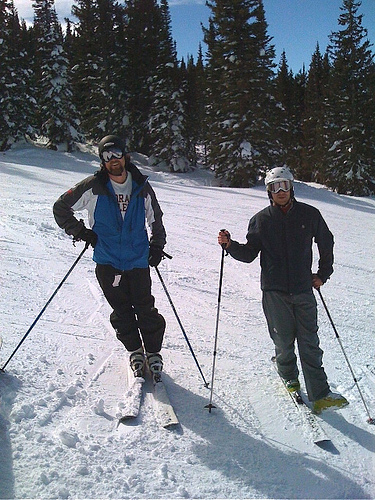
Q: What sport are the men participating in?
A: Skiing.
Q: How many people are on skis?
A: 2.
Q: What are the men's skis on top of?
A: Snow.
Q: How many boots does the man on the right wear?
A: 2.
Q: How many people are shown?
A: 2.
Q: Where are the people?
A: Mountainside.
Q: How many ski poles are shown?
A: 4.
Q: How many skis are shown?
A: 3.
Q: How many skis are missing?
A: 1.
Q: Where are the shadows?
A: On the snow.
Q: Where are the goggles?
A: The men's faces.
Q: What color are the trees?
A: Green.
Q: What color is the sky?
A: Blue.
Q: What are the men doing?
A: Skiing.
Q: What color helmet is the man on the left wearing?
A: Black.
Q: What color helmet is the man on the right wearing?
A: White.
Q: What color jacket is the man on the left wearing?
A: Blue and black.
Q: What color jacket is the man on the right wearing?
A: Black.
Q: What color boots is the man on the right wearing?
A: Yellow.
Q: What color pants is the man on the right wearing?
A: Grey.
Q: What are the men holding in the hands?
A: Ski poles.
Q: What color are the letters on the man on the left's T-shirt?
A: Red.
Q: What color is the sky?
A: Blue.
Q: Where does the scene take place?
A: On a ski slope.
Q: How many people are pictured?
A: Two.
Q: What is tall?
A: Pine trees.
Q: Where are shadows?
A: On the snow.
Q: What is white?
A: Snow.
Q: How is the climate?
A: Snowy.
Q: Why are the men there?
A: Skiing.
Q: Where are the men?
A: On the ski slope.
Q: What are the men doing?
A: Skiing.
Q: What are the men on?
A: Skis.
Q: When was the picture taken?
A: Daytime.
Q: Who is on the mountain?
A: Men.